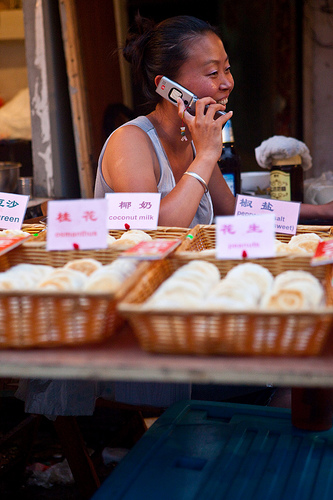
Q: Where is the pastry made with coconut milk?
A: Center basket in the back row.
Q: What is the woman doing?
A: Talking on the phone.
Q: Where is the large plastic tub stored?
A: Under the table.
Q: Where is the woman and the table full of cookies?
A: On a sidewalk in front of buildings.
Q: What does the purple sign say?
A: Coconut milk.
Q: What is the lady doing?
A: Talking on the phone.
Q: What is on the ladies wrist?
A: A bracelet.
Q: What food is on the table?
A: Cookies.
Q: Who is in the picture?
A: A woman.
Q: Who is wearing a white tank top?
A: The woman.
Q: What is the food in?
A: Baskets.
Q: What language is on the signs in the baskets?
A: Chinese.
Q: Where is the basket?
A: On the table.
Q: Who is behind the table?
A: The lady on the phone.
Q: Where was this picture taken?
A: At the market.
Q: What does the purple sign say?
A: Coconut milk.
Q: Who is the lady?
A: A salesperson.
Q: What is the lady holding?
A: A cellphone.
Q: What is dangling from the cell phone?
A: A phone charm.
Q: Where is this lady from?
A: Asia.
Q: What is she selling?
A: Food.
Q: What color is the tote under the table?
A: Blue.